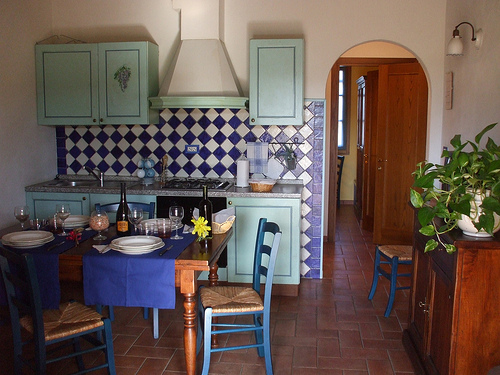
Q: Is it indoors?
A: Yes, it is indoors.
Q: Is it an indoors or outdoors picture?
A: It is indoors.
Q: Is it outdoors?
A: No, it is indoors.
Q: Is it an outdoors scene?
A: No, it is indoors.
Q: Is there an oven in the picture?
A: Yes, there is an oven.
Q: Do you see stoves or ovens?
A: Yes, there is an oven.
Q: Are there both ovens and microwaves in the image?
A: No, there is an oven but no microwaves.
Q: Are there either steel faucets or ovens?
A: Yes, there is a steel oven.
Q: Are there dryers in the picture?
A: No, there are no dryers.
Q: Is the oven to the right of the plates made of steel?
A: Yes, the oven is made of steel.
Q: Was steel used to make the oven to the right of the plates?
A: Yes, the oven is made of steel.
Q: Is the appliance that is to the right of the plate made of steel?
A: Yes, the oven is made of steel.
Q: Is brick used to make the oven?
A: No, the oven is made of steel.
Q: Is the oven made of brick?
A: No, the oven is made of steel.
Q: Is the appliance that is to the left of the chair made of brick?
A: No, the oven is made of steel.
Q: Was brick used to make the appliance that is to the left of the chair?
A: No, the oven is made of steel.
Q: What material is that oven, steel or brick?
A: The oven is made of steel.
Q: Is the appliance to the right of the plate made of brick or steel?
A: The oven is made of steel.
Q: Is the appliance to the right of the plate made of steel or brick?
A: The oven is made of steel.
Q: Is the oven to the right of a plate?
A: Yes, the oven is to the right of a plate.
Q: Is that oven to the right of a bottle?
A: No, the oven is to the right of a plate.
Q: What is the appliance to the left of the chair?
A: The appliance is an oven.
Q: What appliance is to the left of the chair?
A: The appliance is an oven.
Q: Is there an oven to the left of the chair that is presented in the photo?
A: Yes, there is an oven to the left of the chair.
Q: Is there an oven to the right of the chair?
A: No, the oven is to the left of the chair.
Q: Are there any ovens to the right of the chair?
A: No, the oven is to the left of the chair.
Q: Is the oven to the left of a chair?
A: Yes, the oven is to the left of a chair.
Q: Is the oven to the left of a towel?
A: No, the oven is to the left of a chair.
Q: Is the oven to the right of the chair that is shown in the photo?
A: No, the oven is to the left of the chair.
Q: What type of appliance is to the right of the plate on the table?
A: The appliance is an oven.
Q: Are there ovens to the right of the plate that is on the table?
A: Yes, there is an oven to the right of the plate.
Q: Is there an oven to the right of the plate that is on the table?
A: Yes, there is an oven to the right of the plate.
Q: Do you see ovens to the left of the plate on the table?
A: No, the oven is to the right of the plate.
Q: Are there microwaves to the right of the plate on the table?
A: No, there is an oven to the right of the plate.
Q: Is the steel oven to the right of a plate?
A: Yes, the oven is to the right of a plate.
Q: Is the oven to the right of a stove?
A: No, the oven is to the right of a plate.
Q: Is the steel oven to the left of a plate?
A: No, the oven is to the right of a plate.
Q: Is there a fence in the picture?
A: No, there are no fences.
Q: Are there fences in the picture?
A: No, there are no fences.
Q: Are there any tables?
A: Yes, there is a table.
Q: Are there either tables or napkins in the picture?
A: Yes, there is a table.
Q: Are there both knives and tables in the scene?
A: No, there is a table but no knives.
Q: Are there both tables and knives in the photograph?
A: No, there is a table but no knives.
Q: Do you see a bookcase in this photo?
A: No, there are no bookcases.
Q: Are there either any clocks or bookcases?
A: No, there are no bookcases or clocks.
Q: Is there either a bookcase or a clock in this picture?
A: No, there are no bookcases or clocks.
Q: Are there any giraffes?
A: No, there are no giraffes.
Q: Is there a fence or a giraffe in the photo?
A: No, there are no giraffes or fences.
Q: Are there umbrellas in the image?
A: No, there are no umbrellas.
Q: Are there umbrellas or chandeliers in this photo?
A: No, there are no umbrellas or chandeliers.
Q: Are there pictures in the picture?
A: No, there are no pictures.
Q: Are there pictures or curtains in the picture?
A: No, there are no pictures or curtains.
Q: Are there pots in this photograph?
A: Yes, there is a pot.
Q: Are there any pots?
A: Yes, there is a pot.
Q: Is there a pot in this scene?
A: Yes, there is a pot.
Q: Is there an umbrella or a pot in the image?
A: Yes, there is a pot.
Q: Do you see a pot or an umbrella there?
A: Yes, there is a pot.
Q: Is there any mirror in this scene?
A: No, there are no mirrors.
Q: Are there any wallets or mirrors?
A: No, there are no mirrors or wallets.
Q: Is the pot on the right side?
A: Yes, the pot is on the right of the image.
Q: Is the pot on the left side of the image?
A: No, the pot is on the right of the image.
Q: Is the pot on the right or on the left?
A: The pot is on the right of the image.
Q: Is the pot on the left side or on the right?
A: The pot is on the right of the image.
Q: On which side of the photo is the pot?
A: The pot is on the right of the image.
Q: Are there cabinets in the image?
A: Yes, there is a cabinet.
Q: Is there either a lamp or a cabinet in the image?
A: Yes, there is a cabinet.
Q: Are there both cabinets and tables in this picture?
A: Yes, there are both a cabinet and a table.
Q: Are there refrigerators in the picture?
A: No, there are no refrigerators.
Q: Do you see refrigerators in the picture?
A: No, there are no refrigerators.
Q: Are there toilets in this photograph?
A: No, there are no toilets.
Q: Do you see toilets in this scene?
A: No, there are no toilets.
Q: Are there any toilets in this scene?
A: No, there are no toilets.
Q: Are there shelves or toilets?
A: No, there are no toilets or shelves.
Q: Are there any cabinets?
A: Yes, there is a cabinet.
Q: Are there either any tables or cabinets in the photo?
A: Yes, there is a cabinet.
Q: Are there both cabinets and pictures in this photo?
A: No, there is a cabinet but no pictures.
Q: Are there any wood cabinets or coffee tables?
A: Yes, there is a wood cabinet.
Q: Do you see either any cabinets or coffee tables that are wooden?
A: Yes, the cabinet is wooden.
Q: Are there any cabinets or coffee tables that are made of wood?
A: Yes, the cabinet is made of wood.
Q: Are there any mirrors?
A: No, there are no mirrors.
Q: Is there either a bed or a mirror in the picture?
A: No, there are no mirrors or beds.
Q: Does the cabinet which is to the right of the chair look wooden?
A: Yes, the cabinet is wooden.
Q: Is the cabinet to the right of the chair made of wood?
A: Yes, the cabinet is made of wood.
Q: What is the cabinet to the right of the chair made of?
A: The cabinet is made of wood.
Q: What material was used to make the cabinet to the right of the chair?
A: The cabinet is made of wood.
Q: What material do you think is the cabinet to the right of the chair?
A: The cabinet is made of wood.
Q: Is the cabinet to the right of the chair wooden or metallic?
A: The cabinet is wooden.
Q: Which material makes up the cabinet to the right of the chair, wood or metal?
A: The cabinet is made of wood.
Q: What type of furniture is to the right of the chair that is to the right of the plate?
A: The piece of furniture is a cabinet.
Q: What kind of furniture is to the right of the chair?
A: The piece of furniture is a cabinet.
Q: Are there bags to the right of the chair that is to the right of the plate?
A: No, there is a cabinet to the right of the chair.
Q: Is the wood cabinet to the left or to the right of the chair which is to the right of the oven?
A: The cabinet is to the right of the chair.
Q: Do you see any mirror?
A: No, there are no mirrors.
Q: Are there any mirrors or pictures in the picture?
A: No, there are no mirrors or pictures.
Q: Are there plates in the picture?
A: Yes, there is a plate.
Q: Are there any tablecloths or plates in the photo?
A: Yes, there is a plate.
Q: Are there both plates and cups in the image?
A: No, there is a plate but no cups.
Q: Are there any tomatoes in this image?
A: No, there are no tomatoes.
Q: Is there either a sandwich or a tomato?
A: No, there are no tomatoes or sandwiches.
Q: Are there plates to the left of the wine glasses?
A: Yes, there is a plate to the left of the wine glasses.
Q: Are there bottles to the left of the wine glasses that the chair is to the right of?
A: No, there is a plate to the left of the wine glasses.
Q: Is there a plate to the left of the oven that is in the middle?
A: Yes, there is a plate to the left of the oven.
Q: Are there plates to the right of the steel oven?
A: No, the plate is to the left of the oven.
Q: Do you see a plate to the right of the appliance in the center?
A: No, the plate is to the left of the oven.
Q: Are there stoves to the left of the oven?
A: No, there is a plate to the left of the oven.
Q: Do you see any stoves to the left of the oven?
A: No, there is a plate to the left of the oven.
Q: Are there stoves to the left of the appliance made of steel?
A: No, there is a plate to the left of the oven.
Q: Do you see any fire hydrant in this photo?
A: No, there are no fire hydrants.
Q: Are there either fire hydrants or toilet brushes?
A: No, there are no fire hydrants or toilet brushes.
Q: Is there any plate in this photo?
A: Yes, there is a plate.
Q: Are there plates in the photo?
A: Yes, there is a plate.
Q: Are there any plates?
A: Yes, there is a plate.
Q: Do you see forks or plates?
A: Yes, there is a plate.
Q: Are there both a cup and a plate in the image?
A: No, there is a plate but no cups.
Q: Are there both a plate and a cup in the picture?
A: No, there is a plate but no cups.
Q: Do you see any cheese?
A: No, there is no cheese.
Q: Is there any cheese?
A: No, there is no cheese.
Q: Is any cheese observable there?
A: No, there is no cheese.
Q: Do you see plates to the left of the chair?
A: Yes, there is a plate to the left of the chair.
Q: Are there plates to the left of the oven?
A: Yes, there is a plate to the left of the oven.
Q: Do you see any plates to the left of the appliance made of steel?
A: Yes, there is a plate to the left of the oven.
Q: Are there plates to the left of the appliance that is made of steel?
A: Yes, there is a plate to the left of the oven.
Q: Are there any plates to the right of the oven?
A: No, the plate is to the left of the oven.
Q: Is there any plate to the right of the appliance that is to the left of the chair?
A: No, the plate is to the left of the oven.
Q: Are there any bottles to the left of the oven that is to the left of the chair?
A: No, there is a plate to the left of the oven.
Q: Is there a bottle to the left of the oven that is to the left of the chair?
A: No, there is a plate to the left of the oven.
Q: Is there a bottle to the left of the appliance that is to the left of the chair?
A: No, there is a plate to the left of the oven.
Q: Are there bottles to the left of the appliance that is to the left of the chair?
A: No, there is a plate to the left of the oven.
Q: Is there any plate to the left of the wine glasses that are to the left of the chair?
A: Yes, there is a plate to the left of the wine glasses.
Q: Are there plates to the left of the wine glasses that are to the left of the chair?
A: Yes, there is a plate to the left of the wine glasses.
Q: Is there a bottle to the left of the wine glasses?
A: No, there is a plate to the left of the wine glasses.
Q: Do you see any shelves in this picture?
A: No, there are no shelves.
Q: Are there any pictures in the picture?
A: No, there are no pictures.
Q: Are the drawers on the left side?
A: Yes, the drawers are on the left of the image.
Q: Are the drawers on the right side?
A: No, the drawers are on the left of the image.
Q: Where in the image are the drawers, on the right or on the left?
A: The drawers are on the left of the image.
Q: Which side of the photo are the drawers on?
A: The drawers are on the left of the image.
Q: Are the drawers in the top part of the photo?
A: Yes, the drawers are in the top of the image.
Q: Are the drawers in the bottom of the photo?
A: No, the drawers are in the top of the image.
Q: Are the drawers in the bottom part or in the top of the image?
A: The drawers are in the top of the image.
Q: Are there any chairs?
A: Yes, there is a chair.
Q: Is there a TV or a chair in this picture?
A: Yes, there is a chair.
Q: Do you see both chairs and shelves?
A: No, there is a chair but no shelves.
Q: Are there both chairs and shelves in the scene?
A: No, there is a chair but no shelves.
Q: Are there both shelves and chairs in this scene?
A: No, there is a chair but no shelves.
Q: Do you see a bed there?
A: No, there are no beds.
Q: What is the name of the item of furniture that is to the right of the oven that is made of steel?
A: The piece of furniture is a chair.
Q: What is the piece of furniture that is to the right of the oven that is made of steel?
A: The piece of furniture is a chair.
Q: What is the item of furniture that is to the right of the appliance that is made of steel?
A: The piece of furniture is a chair.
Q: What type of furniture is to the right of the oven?
A: The piece of furniture is a chair.